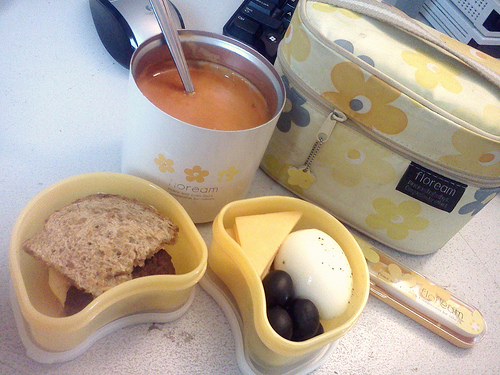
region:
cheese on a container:
[218, 205, 341, 351]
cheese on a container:
[226, 221, 296, 323]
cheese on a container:
[210, 170, 297, 296]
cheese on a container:
[221, 195, 286, 278]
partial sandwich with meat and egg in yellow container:
[26, 185, 188, 331]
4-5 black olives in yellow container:
[250, 265, 315, 350]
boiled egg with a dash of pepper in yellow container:
[281, 215, 366, 310]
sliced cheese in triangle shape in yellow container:
[215, 195, 310, 270]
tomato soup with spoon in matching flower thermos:
[113, 3, 279, 175]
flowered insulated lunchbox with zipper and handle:
[271, 12, 496, 228]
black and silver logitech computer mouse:
[90, 2, 190, 68]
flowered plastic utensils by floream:
[360, 225, 495, 360]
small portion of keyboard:
[215, 0, 310, 56]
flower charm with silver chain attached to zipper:
[273, 160, 339, 196]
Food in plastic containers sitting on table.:
[8, 159, 358, 374]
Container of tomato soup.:
[114, 27, 286, 220]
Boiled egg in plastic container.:
[277, 231, 357, 323]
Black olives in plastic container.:
[266, 269, 328, 345]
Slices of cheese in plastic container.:
[232, 208, 302, 271]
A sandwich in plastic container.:
[27, 194, 193, 316]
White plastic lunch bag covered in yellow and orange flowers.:
[280, 8, 498, 252]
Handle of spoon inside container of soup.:
[141, 3, 209, 103]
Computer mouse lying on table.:
[85, 3, 189, 69]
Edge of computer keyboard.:
[223, 1, 303, 62]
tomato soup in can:
[135, 60, 266, 130]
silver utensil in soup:
[145, 0, 192, 95]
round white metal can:
[125, 30, 285, 225]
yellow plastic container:
[10, 170, 205, 350]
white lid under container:
[1, 272, 193, 362]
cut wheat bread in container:
[20, 190, 175, 301]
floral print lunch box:
[260, 0, 495, 250]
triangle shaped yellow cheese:
[232, 210, 298, 280]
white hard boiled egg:
[272, 225, 352, 315]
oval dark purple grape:
[291, 296, 317, 337]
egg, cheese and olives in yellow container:
[212, 200, 377, 361]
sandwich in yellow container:
[10, 165, 195, 352]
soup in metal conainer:
[110, 27, 290, 207]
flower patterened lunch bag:
[247, 27, 494, 242]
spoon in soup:
[150, 26, 205, 96]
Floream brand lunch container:
[381, 151, 471, 221]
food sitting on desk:
[5, 60, 401, 360]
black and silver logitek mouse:
[96, 1, 191, 63]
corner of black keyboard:
[223, 0, 310, 65]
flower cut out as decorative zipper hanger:
[270, 95, 354, 194]